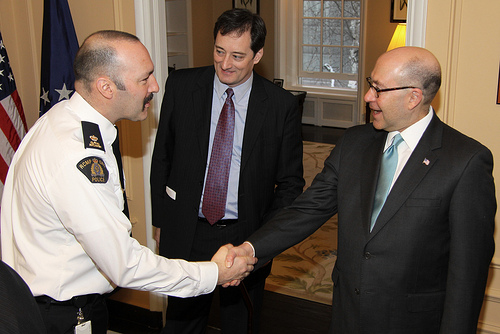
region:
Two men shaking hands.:
[49, 33, 470, 306]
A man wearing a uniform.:
[33, 27, 188, 331]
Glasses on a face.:
[358, 74, 422, 104]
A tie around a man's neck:
[201, 72, 237, 229]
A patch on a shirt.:
[75, 149, 119, 186]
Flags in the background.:
[3, 25, 100, 156]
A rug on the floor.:
[251, 126, 372, 320]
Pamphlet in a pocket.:
[161, 180, 176, 207]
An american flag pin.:
[423, 158, 431, 167]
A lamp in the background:
[375, 22, 413, 58]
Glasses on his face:
[365, 74, 428, 100]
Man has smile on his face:
[208, 6, 269, 87]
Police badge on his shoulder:
[72, 155, 112, 185]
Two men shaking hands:
[4, 23, 497, 331]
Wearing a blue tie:
[363, 128, 408, 235]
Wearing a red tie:
[199, 85, 236, 225]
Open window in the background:
[293, 1, 365, 95]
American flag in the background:
[0, 24, 31, 204]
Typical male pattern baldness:
[71, 28, 148, 69]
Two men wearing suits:
[149, 7, 499, 332]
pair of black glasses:
[357, 68, 420, 100]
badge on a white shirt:
[71, 152, 111, 185]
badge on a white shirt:
[75, 118, 110, 154]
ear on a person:
[95, 74, 116, 99]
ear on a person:
[405, 83, 425, 109]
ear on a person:
[251, 45, 270, 65]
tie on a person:
[191, 87, 243, 233]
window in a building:
[292, 0, 364, 89]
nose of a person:
[145, 74, 160, 94]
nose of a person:
[219, 55, 234, 72]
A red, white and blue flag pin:
[420, 155, 431, 168]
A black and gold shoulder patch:
[71, 153, 113, 187]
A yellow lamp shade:
[382, 18, 409, 53]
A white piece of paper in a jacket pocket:
[161, 182, 181, 203]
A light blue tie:
[367, 132, 405, 235]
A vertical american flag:
[0, 24, 31, 209]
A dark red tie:
[198, 85, 236, 228]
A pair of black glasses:
[359, 72, 423, 100]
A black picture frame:
[386, 0, 411, 25]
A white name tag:
[68, 305, 94, 333]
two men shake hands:
[1, 3, 498, 332]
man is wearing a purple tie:
[149, 3, 307, 332]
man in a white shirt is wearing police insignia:
[3, 24, 259, 332]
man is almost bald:
[346, 42, 448, 137]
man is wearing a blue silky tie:
[346, 40, 447, 237]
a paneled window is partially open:
[291, 3, 363, 94]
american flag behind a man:
[0, 28, 30, 249]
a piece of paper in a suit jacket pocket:
[152, 179, 182, 213]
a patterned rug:
[254, 131, 341, 303]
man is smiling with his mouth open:
[354, 42, 446, 137]